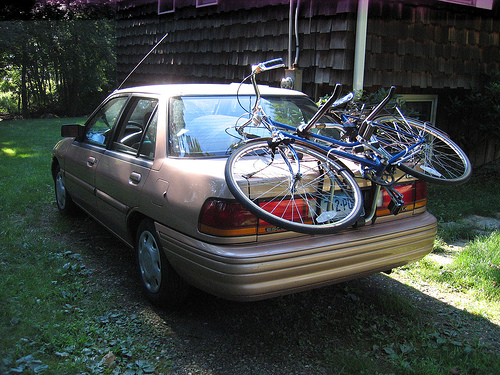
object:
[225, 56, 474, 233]
bike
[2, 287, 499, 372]
ground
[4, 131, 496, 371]
shady area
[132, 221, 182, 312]
tire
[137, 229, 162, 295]
silver rim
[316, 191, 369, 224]
license plate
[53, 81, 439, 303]
car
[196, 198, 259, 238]
taillights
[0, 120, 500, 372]
grass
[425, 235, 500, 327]
sun lit patch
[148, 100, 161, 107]
rear view mirror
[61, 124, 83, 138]
side mirror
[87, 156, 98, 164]
door handle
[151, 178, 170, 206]
gas tank door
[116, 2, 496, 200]
building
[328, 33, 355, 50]
brown wood siding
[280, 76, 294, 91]
utility meter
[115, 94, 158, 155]
window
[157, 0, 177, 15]
window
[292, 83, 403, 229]
bike rack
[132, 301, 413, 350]
gravel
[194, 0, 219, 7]
windows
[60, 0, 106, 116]
trees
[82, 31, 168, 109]
an antenna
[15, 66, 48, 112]
meadow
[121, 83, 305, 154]
sunlight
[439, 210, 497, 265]
sidewalk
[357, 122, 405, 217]
pedals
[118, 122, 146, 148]
steering wheel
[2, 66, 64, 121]
sunlight